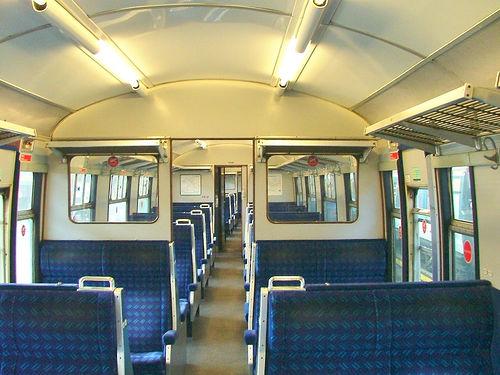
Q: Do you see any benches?
A: Yes, there is a bench.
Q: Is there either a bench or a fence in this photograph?
A: Yes, there is a bench.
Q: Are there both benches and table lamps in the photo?
A: No, there is a bench but no table lamps.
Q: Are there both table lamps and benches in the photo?
A: No, there is a bench but no table lamps.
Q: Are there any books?
A: No, there are no books.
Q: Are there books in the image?
A: No, there are no books.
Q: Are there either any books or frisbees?
A: No, there are no books or frisbees.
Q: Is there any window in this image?
A: Yes, there is a window.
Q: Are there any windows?
A: Yes, there is a window.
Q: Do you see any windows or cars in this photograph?
A: Yes, there is a window.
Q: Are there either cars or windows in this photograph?
A: Yes, there is a window.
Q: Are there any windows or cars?
A: Yes, there is a window.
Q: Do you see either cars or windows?
A: Yes, there is a window.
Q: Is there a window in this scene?
A: Yes, there is a window.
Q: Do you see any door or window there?
A: Yes, there is a window.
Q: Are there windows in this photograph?
A: Yes, there is a window.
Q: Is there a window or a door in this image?
A: Yes, there is a window.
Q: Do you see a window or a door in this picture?
A: Yes, there is a window.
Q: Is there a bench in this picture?
A: Yes, there is a bench.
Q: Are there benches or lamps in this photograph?
A: Yes, there is a bench.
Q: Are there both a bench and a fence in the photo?
A: No, there is a bench but no fences.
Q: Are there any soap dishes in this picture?
A: No, there are no soap dishes.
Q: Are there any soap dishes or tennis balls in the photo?
A: No, there are no soap dishes or tennis balls.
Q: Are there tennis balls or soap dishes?
A: No, there are no soap dishes or tennis balls.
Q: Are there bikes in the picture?
A: No, there are no bikes.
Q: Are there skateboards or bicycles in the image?
A: No, there are no bicycles or skateboards.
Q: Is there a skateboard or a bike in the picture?
A: No, there are no bikes or skateboards.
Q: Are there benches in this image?
A: Yes, there is a bench.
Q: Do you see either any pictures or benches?
A: Yes, there is a bench.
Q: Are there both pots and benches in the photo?
A: No, there is a bench but no pots.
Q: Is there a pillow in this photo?
A: No, there are no pillows.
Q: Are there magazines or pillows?
A: No, there are no pillows or magazines.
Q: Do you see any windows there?
A: Yes, there is a window.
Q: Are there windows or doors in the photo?
A: Yes, there is a window.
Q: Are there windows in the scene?
A: Yes, there is a window.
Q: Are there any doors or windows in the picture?
A: Yes, there is a window.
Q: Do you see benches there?
A: Yes, there is a bench.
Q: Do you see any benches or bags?
A: Yes, there is a bench.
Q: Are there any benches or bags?
A: Yes, there is a bench.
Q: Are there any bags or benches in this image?
A: Yes, there is a bench.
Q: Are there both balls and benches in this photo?
A: No, there is a bench but no balls.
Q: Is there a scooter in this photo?
A: No, there are no scooters.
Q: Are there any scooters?
A: No, there are no scooters.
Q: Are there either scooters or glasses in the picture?
A: No, there are no scooters or glasses.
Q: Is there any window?
A: Yes, there is a window.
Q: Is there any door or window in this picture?
A: Yes, there is a window.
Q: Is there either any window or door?
A: Yes, there is a window.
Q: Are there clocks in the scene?
A: No, there are no clocks.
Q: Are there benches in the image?
A: Yes, there is a bench.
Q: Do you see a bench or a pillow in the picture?
A: Yes, there is a bench.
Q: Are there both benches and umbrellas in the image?
A: No, there is a bench but no umbrellas.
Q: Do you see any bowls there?
A: No, there are no bowls.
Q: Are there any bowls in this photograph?
A: No, there are no bowls.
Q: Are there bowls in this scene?
A: No, there are no bowls.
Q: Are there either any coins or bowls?
A: No, there are no bowls or coins.